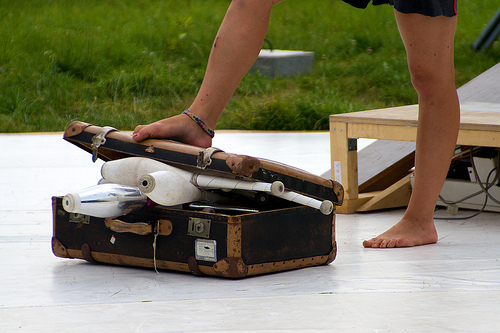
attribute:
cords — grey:
[446, 162, 496, 229]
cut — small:
[209, 32, 224, 57]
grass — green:
[0, 0, 500, 135]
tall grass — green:
[1, 2, 471, 125]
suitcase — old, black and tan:
[57, 97, 372, 288]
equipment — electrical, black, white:
[46, 111, 343, 291]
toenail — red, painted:
[358, 227, 381, 257]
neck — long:
[190, 172, 267, 194]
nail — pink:
[129, 121, 161, 147]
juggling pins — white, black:
[60, 155, 333, 217]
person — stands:
[180, 0, 458, 248]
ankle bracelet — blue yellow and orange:
[186, 108, 216, 132]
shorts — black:
[335, 1, 462, 15]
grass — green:
[3, 3, 499, 150]